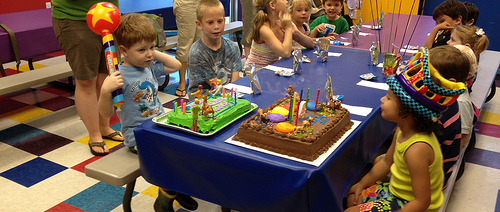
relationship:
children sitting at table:
[86, 0, 488, 208] [117, 20, 400, 196]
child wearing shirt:
[359, 57, 466, 202] [369, 125, 464, 210]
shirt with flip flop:
[47, 0, 117, 20] [86, 136, 108, 157]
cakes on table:
[243, 90, 360, 163] [133, 10, 493, 210]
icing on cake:
[231, 131, 353, 160] [231, 73, 352, 160]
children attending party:
[86, 0, 488, 208] [6, 6, 494, 209]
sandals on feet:
[86, 132, 130, 156] [81, 123, 130, 157]